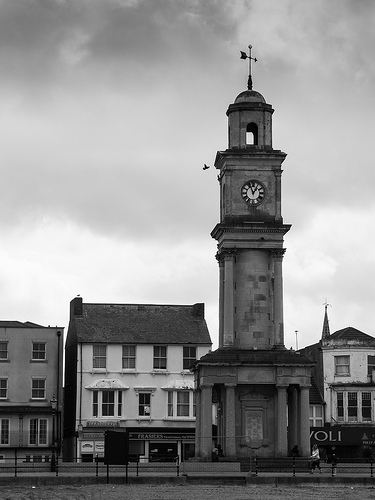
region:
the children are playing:
[282, 436, 350, 477]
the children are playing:
[268, 428, 364, 498]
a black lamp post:
[34, 378, 60, 478]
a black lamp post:
[43, 389, 65, 473]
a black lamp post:
[39, 385, 81, 495]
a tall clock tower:
[209, 87, 316, 497]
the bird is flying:
[190, 154, 220, 178]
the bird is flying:
[193, 154, 231, 207]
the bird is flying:
[187, 152, 223, 192]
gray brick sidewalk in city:
[2, 475, 373, 494]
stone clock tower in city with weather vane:
[189, 41, 336, 469]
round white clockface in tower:
[244, 178, 270, 208]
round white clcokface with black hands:
[241, 178, 266, 208]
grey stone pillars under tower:
[189, 365, 310, 459]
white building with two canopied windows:
[61, 294, 211, 459]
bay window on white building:
[335, 386, 374, 421]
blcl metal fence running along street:
[5, 451, 374, 483]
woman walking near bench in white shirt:
[304, 442, 329, 480]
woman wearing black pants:
[312, 461, 322, 469]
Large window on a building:
[86, 342, 119, 375]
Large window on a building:
[114, 342, 143, 374]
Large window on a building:
[148, 343, 175, 373]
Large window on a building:
[179, 343, 202, 374]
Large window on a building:
[85, 377, 125, 414]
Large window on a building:
[125, 380, 161, 420]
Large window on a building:
[164, 379, 203, 429]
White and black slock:
[232, 173, 268, 204]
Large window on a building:
[24, 337, 51, 365]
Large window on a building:
[22, 370, 51, 402]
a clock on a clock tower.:
[234, 174, 268, 209]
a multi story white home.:
[63, 295, 215, 464]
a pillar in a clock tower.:
[277, 379, 292, 456]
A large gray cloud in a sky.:
[0, 0, 369, 249]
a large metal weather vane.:
[237, 36, 266, 89]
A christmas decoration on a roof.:
[317, 295, 335, 345]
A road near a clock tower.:
[0, 475, 373, 499]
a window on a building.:
[132, 387, 155, 419]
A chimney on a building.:
[67, 292, 86, 323]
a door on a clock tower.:
[238, 403, 266, 449]